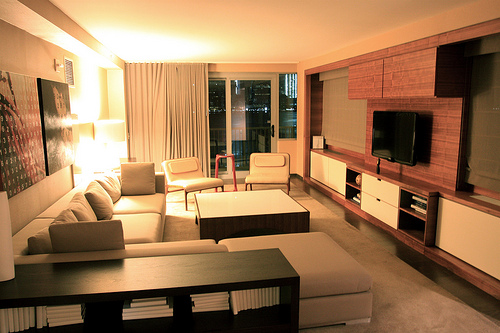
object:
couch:
[28, 163, 169, 254]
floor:
[159, 169, 500, 333]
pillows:
[120, 163, 155, 195]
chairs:
[161, 156, 224, 211]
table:
[212, 152, 237, 193]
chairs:
[243, 153, 290, 194]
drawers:
[360, 172, 400, 208]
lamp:
[92, 119, 127, 168]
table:
[95, 157, 122, 175]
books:
[128, 299, 166, 306]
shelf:
[1, 248, 302, 333]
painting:
[36, 77, 72, 178]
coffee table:
[194, 187, 311, 239]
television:
[372, 110, 419, 166]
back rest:
[248, 152, 290, 172]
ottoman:
[192, 189, 309, 240]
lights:
[284, 73, 300, 100]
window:
[228, 79, 274, 172]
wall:
[299, 18, 500, 301]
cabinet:
[0, 247, 299, 333]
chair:
[8, 162, 373, 329]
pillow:
[82, 183, 114, 221]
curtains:
[121, 61, 209, 177]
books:
[34, 305, 42, 329]